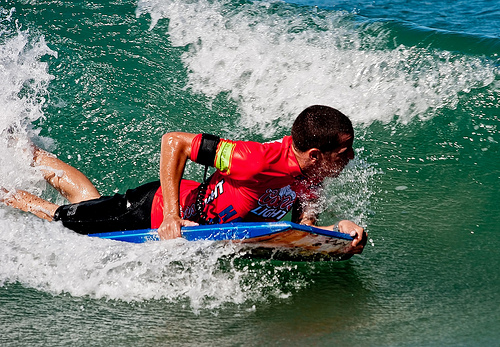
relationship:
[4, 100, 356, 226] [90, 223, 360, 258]
man on surfboard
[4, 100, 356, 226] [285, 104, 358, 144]
man has hair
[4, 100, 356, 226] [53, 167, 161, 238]
man has shorts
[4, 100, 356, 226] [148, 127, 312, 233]
man has shirt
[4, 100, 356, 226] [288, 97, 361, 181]
man has head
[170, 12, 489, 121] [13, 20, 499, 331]
wave in ocean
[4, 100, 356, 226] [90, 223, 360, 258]
man has surfboard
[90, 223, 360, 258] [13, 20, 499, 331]
surfboard in ocean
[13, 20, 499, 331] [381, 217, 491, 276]
ocean has ripples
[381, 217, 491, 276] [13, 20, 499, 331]
ripples in ocean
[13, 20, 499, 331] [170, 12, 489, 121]
ocean has wave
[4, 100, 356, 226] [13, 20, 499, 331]
man in ocean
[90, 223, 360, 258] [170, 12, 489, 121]
surfboard on wave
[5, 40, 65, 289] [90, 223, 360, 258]
water behind surfboard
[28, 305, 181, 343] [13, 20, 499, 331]
ripples in ocean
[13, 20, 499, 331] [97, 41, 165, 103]
ocean has ripples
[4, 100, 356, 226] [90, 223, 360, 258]
man riding on surfboard